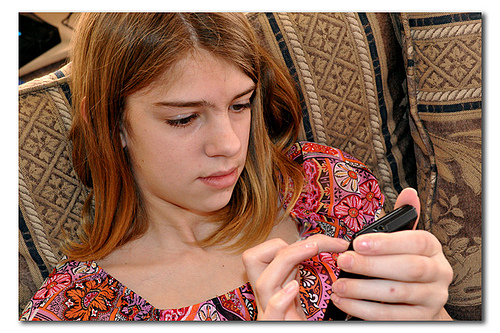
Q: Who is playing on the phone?
A: The girl.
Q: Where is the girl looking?
A: At the phone.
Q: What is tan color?
A: Couch.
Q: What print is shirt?
A: Paisley.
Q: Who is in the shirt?
A: A girl.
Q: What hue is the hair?
A: Brown.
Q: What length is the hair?
A: Medium.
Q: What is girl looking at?
A: Cellphone.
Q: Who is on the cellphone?
A: A girl.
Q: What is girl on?
A: A pillow.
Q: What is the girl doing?
A: Using a cellphone.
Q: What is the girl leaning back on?
A: A pillow.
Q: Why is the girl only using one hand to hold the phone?
A: The other hand is touching the screen.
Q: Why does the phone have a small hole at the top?
A: It is a headphone jack.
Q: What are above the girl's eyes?
A: Eyebrows.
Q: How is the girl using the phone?
A: She is touching the screen with her finger.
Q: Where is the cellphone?
A: In the girl's hand.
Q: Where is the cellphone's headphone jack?
A: On the top part of the phone.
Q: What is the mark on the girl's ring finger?
A: A blemish.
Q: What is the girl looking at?
A: A phone.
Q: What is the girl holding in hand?
A: Black phone.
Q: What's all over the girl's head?
A: Brown hair.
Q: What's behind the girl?
A: Pillows.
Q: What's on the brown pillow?
A: Black lines.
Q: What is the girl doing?
A: Looking at the black phone.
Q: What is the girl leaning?
A: Pillows.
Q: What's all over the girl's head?
A: Red hair.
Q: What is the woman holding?
A: A phone.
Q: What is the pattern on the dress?
A: Floral.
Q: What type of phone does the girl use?
A: A smartphone.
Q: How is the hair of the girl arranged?
A: Parted.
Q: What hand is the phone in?
A: Left.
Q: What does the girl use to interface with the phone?
A: The finger.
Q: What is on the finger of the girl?
A: Blemish.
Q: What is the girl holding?
A: A cellphone.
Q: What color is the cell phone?
A: Black.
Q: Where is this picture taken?
A: On a couch.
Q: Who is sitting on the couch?
A: A girl.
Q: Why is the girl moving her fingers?
A: Because she is texting.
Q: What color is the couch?
A: Brown, black and white.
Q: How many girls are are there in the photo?
A: One.